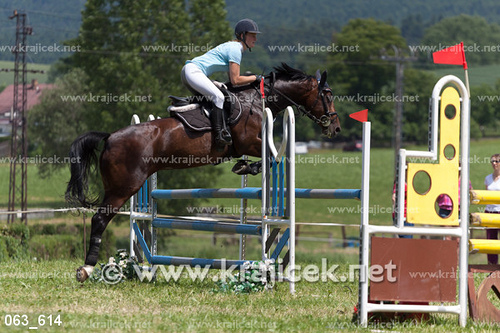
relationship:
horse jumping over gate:
[65, 60, 342, 284] [125, 110, 305, 292]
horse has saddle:
[64, 62, 341, 284] [163, 90, 254, 134]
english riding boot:
[166, 86, 256, 168] [207, 105, 256, 155]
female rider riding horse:
[181, 19, 265, 145] [65, 60, 342, 284]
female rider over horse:
[177, 14, 267, 147] [65, 60, 342, 284]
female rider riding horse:
[181, 19, 265, 145] [27, 54, 395, 209]